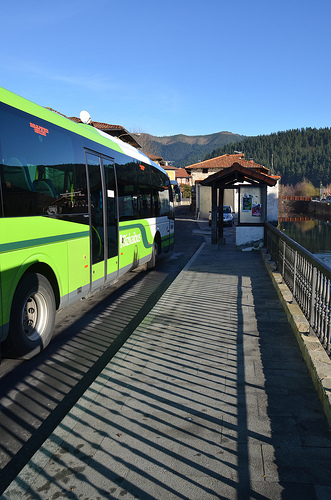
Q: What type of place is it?
A: It is a sidewalk.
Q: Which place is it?
A: It is a sidewalk.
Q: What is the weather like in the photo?
A: It is clear.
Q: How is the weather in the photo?
A: It is clear.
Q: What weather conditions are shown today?
A: It is clear.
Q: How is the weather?
A: It is clear.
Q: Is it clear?
A: Yes, it is clear.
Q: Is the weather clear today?
A: Yes, it is clear.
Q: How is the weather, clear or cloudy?
A: It is clear.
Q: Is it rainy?
A: No, it is clear.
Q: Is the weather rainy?
A: No, it is clear.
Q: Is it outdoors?
A: Yes, it is outdoors.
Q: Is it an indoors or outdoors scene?
A: It is outdoors.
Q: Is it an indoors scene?
A: No, it is outdoors.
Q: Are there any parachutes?
A: No, there are no parachutes.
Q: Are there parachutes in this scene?
A: No, there are no parachutes.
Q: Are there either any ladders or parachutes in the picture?
A: No, there are no parachutes or ladders.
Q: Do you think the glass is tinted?
A: Yes, the glass is tinted.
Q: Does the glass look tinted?
A: Yes, the glass is tinted.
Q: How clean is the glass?
A: The glass is tinted.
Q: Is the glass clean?
A: No, the glass is tinted.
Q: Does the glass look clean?
A: No, the glass is tinted.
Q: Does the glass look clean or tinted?
A: The glass is tinted.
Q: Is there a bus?
A: Yes, there is a bus.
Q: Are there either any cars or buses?
A: Yes, there is a bus.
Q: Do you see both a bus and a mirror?
A: Yes, there are both a bus and a mirror.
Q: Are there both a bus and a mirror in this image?
A: Yes, there are both a bus and a mirror.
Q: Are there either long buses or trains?
A: Yes, there is a long bus.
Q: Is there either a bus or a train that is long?
A: Yes, the bus is long.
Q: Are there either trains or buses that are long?
A: Yes, the bus is long.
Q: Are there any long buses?
A: Yes, there is a long bus.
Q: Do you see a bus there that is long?
A: Yes, there is a bus that is long.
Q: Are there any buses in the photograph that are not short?
A: Yes, there is a long bus.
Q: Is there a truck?
A: No, there are no trucks.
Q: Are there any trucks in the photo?
A: No, there are no trucks.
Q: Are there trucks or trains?
A: No, there are no trucks or trains.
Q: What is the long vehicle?
A: The vehicle is a bus.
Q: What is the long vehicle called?
A: The vehicle is a bus.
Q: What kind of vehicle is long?
A: The vehicle is a bus.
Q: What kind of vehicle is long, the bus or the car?
A: The bus is long.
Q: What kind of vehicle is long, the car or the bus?
A: The bus is long.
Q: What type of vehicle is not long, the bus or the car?
A: The car is not long.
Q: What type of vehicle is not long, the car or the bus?
A: The car is not long.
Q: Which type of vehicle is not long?
A: The vehicle is a car.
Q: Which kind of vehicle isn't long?
A: The vehicle is a car.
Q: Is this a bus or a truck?
A: This is a bus.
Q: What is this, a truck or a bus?
A: This is a bus.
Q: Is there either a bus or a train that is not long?
A: No, there is a bus but it is long.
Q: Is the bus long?
A: Yes, the bus is long.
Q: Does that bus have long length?
A: Yes, the bus is long.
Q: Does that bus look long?
A: Yes, the bus is long.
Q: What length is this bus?
A: The bus is long.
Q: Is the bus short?
A: No, the bus is long.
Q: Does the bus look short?
A: No, the bus is long.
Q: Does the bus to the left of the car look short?
A: No, the bus is long.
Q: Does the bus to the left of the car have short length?
A: No, the bus is long.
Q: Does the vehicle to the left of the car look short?
A: No, the bus is long.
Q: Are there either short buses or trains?
A: No, there is a bus but it is long.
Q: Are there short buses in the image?
A: No, there is a bus but it is long.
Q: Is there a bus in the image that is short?
A: No, there is a bus but it is long.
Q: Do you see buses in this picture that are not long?
A: No, there is a bus but it is long.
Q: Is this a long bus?
A: Yes, this is a long bus.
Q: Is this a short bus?
A: No, this is a long bus.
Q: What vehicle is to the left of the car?
A: The vehicle is a bus.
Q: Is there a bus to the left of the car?
A: Yes, there is a bus to the left of the car.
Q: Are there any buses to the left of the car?
A: Yes, there is a bus to the left of the car.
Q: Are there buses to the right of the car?
A: No, the bus is to the left of the car.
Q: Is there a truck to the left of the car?
A: No, there is a bus to the left of the car.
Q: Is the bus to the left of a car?
A: Yes, the bus is to the left of a car.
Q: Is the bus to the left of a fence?
A: No, the bus is to the left of a car.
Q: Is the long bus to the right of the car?
A: No, the bus is to the left of the car.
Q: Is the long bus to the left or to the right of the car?
A: The bus is to the left of the car.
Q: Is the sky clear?
A: Yes, the sky is clear.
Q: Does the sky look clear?
A: Yes, the sky is clear.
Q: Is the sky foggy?
A: No, the sky is clear.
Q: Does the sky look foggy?
A: No, the sky is clear.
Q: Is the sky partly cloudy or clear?
A: The sky is clear.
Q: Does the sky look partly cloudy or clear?
A: The sky is clear.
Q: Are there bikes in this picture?
A: No, there are no bikes.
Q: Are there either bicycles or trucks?
A: No, there are no bicycles or trucks.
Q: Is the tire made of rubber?
A: Yes, the tire is made of rubber.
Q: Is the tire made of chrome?
A: No, the tire is made of rubber.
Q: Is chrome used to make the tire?
A: No, the tire is made of rubber.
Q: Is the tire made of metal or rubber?
A: The tire is made of rubber.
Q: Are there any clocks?
A: No, there are no clocks.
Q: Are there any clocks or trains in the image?
A: No, there are no clocks or trains.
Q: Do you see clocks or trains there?
A: No, there are no clocks or trains.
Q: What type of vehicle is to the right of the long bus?
A: The vehicle is a car.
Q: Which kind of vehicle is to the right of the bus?
A: The vehicle is a car.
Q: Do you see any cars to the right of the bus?
A: Yes, there is a car to the right of the bus.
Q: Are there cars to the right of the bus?
A: Yes, there is a car to the right of the bus.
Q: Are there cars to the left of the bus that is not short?
A: No, the car is to the right of the bus.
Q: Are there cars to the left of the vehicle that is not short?
A: No, the car is to the right of the bus.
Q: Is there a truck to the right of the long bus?
A: No, there is a car to the right of the bus.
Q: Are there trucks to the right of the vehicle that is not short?
A: No, there is a car to the right of the bus.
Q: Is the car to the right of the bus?
A: Yes, the car is to the right of the bus.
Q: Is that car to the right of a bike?
A: No, the car is to the right of the bus.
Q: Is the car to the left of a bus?
A: No, the car is to the right of a bus.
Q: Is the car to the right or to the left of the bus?
A: The car is to the right of the bus.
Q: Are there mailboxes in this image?
A: No, there are no mailboxes.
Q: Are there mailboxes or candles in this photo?
A: No, there are no mailboxes or candles.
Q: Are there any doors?
A: Yes, there are doors.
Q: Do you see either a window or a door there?
A: Yes, there are doors.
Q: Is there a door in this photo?
A: Yes, there is a door.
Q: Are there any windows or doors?
A: Yes, there is a door.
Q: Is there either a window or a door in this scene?
A: Yes, there is a door.